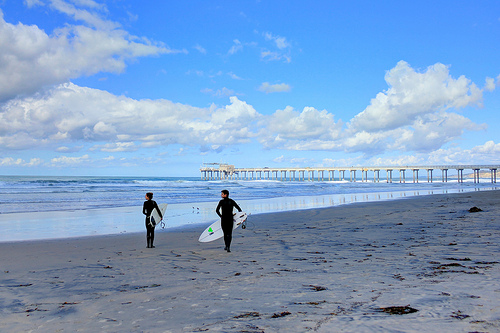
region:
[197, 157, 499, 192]
large pier on beach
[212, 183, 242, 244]
man wearing black wetsuit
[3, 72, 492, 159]
white clouds in the sky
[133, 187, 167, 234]
woman wearing black wetsuit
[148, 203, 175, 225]
woman holding white surfboard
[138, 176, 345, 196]
waves crashing against pier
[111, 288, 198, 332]
footprints in the sand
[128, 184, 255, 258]
man and woman walking down beach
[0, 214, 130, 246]
shore of the beach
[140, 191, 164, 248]
A woman in a black wetsuit holding a surfboard.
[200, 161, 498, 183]
A long light colored pier.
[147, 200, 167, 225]
A white and black surfboard a woman is holding.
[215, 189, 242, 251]
A man with dark hair in a black wetsuit.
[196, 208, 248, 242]
A white surfboard with green on it.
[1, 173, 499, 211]
The blue wavy ocean.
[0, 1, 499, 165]
Blue sky with white clouds in it.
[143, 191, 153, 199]
A woman's head with her hair back and face turned to her left.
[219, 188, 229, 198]
A man's head with black hair and his face turned to the left.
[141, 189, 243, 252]
A man and woman in wetsuits on the beach.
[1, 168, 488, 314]
beach area with sand and water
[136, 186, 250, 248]
surfers with surf boards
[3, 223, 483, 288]
sand area of the beach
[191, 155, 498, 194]
pier in the water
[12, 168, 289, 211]
water on the beach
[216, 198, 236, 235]
wet suit on surfer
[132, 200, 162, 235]
wet suit on surfer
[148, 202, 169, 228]
board in surfer's arms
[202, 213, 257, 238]
board in surfer's arms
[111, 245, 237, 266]
foot steps in sand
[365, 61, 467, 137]
a thick white cloud in the sky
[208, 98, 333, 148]
a thick white cloud in the sky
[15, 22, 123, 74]
a thick white cloud in the sky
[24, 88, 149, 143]
a thick white cloud in the sky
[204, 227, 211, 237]
a neon green sticker on a surfboard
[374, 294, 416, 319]
dried seaweed on the beach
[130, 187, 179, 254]
a woman holding a white surfboard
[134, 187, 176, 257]
a woman in a black wetsuit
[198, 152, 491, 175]
a long wooden pier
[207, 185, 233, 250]
a man wearing a black wetsuit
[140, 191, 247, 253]
two surfers watching the waves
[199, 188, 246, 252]
a surfer carrying a surfboard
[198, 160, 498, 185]
a very long pier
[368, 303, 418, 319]
seaweed washed up on the beach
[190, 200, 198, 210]
birds on the beach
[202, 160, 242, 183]
the end of the pier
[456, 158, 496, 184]
the beginning of the pier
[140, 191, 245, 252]
2 surfers carrying their surf boards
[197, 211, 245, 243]
a surf board being carried to the water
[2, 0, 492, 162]
the blue sky filled with white clouds